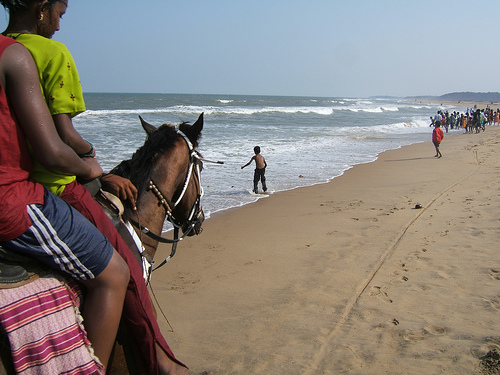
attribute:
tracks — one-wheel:
[304, 180, 467, 373]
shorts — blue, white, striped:
[30, 225, 98, 274]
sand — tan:
[376, 210, 491, 365]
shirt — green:
[10, 33, 102, 188]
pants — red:
[52, 174, 196, 374]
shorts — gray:
[3, 186, 114, 281]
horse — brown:
[68, 109, 209, 341]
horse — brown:
[0, 106, 240, 373]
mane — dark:
[86, 117, 208, 213]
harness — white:
[160, 121, 206, 241]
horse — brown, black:
[0, 110, 204, 373]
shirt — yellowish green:
[1, 29, 85, 119]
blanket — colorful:
[1, 297, 75, 338]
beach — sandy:
[132, 106, 498, 361]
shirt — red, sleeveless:
[0, 36, 44, 239]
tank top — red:
[0, 33, 47, 245]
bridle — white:
[152, 122, 207, 233]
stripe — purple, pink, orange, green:
[0, 287, 79, 327]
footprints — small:
[368, 170, 463, 358]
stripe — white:
[28, 207, 90, 291]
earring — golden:
[32, 6, 52, 26]